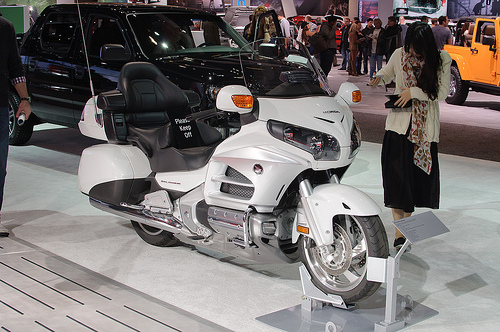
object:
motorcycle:
[78, 36, 388, 304]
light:
[231, 94, 254, 110]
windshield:
[238, 36, 334, 96]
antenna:
[76, 0, 96, 97]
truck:
[443, 16, 500, 105]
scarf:
[402, 46, 442, 176]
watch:
[21, 96, 31, 101]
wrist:
[15, 95, 34, 110]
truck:
[9, 4, 318, 146]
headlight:
[267, 117, 343, 164]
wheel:
[297, 183, 388, 303]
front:
[204, 36, 391, 304]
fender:
[291, 183, 381, 246]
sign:
[166, 106, 205, 153]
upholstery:
[93, 61, 223, 172]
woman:
[367, 21, 452, 252]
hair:
[404, 21, 442, 101]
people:
[304, 15, 341, 79]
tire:
[131, 220, 178, 248]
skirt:
[380, 113, 440, 213]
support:
[299, 241, 411, 332]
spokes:
[304, 214, 366, 291]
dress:
[374, 47, 451, 214]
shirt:
[372, 46, 452, 142]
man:
[0, 16, 35, 240]